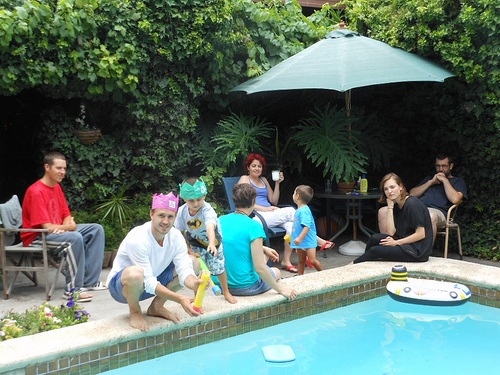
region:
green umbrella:
[224, 25, 455, 97]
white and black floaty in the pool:
[385, 262, 472, 305]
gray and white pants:
[24, 220, 106, 295]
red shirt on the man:
[16, 178, 71, 248]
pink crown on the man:
[148, 189, 183, 213]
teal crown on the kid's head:
[176, 175, 207, 202]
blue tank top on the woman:
[247, 176, 271, 206]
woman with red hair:
[242, 149, 266, 171]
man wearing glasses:
[433, 161, 449, 171]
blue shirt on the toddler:
[288, 206, 318, 250]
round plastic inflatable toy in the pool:
[386, 273, 471, 301]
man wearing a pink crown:
[108, 190, 210, 327]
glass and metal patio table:
[310, 189, 387, 247]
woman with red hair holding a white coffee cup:
[238, 152, 333, 274]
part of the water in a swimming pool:
[86, 289, 498, 369]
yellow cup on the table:
[358, 177, 368, 192]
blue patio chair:
[223, 174, 288, 261]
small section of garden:
[1, 300, 88, 337]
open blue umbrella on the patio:
[231, 22, 451, 95]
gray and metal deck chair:
[0, 194, 74, 301]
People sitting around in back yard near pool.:
[0, 2, 498, 374]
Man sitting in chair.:
[4, 149, 107, 304]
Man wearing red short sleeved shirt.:
[20, 149, 110, 301]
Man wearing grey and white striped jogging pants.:
[23, 225, 114, 302]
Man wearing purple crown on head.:
[108, 191, 205, 332]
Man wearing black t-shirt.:
[408, 166, 470, 227]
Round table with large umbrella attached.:
[0, 0, 499, 374]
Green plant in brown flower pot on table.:
[291, 101, 416, 261]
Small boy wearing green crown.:
[171, 171, 237, 306]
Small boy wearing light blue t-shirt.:
[290, 181, 323, 272]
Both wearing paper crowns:
[149, 174, 208, 213]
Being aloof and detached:
[405, 149, 467, 261]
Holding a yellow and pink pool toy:
[189, 267, 211, 316]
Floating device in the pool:
[385, 264, 473, 306]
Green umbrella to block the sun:
[221, 19, 465, 96]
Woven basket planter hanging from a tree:
[73, 119, 103, 149]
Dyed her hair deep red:
[242, 152, 269, 169]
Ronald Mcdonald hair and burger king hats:
[147, 151, 268, 215]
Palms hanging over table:
[282, 100, 374, 189]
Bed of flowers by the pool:
[1, 283, 92, 341]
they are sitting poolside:
[109, 172, 453, 339]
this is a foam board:
[255, 335, 312, 365]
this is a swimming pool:
[90, 278, 498, 373]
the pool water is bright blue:
[110, 275, 497, 372]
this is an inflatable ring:
[377, 255, 469, 307]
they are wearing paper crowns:
[114, 154, 219, 311]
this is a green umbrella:
[222, 21, 460, 99]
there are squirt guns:
[180, 251, 234, 318]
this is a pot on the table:
[335, 173, 359, 192]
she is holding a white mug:
[234, 148, 338, 273]